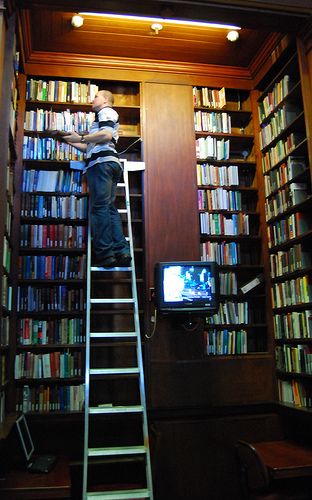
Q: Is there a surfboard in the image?
A: No, there are no surfboards.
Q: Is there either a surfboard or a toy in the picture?
A: No, there are no surfboards or toys.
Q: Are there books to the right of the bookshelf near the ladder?
A: Yes, there is a book to the right of the bookshelf.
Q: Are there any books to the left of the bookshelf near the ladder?
A: No, the book is to the right of the bookshelf.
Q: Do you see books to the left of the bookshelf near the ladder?
A: No, the book is to the right of the bookshelf.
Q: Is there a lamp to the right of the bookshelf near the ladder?
A: No, there is a book to the right of the bookshelf.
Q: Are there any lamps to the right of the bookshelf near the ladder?
A: No, there is a book to the right of the bookshelf.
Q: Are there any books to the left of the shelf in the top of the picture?
A: Yes, there is a book to the left of the shelf.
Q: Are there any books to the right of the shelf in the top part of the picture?
A: No, the book is to the left of the shelf.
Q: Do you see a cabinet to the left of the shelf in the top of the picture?
A: No, there is a book to the left of the shelf.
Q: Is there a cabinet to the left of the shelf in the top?
A: No, there is a book to the left of the shelf.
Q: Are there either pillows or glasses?
A: No, there are no glasses or pillows.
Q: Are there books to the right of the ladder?
A: Yes, there is a book to the right of the ladder.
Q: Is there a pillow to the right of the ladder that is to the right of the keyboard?
A: No, there is a book to the right of the ladder.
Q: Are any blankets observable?
A: No, there are no blankets.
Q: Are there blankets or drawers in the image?
A: No, there are no blankets or drawers.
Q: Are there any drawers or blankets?
A: No, there are no blankets or drawers.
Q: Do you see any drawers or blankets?
A: No, there are no blankets or drawers.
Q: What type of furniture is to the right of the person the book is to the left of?
A: The piece of furniture is a bookshelf.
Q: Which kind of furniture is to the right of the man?
A: The piece of furniture is a bookshelf.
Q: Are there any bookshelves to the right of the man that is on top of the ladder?
A: Yes, there is a bookshelf to the right of the man.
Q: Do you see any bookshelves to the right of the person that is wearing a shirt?
A: Yes, there is a bookshelf to the right of the man.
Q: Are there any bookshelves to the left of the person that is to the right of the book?
A: No, the bookshelf is to the right of the man.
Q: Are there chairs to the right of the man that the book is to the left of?
A: No, there is a bookshelf to the right of the man.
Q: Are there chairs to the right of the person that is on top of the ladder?
A: No, there is a bookshelf to the right of the man.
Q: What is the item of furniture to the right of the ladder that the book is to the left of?
A: The piece of furniture is a bookshelf.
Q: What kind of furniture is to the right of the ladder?
A: The piece of furniture is a bookshelf.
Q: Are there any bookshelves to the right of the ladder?
A: Yes, there is a bookshelf to the right of the ladder.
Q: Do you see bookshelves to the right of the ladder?
A: Yes, there is a bookshelf to the right of the ladder.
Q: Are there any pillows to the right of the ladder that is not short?
A: No, there is a bookshelf to the right of the ladder.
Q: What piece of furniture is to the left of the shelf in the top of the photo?
A: The piece of furniture is a bookshelf.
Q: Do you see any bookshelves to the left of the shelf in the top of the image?
A: Yes, there is a bookshelf to the left of the shelf.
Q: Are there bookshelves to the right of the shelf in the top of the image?
A: No, the bookshelf is to the left of the shelf.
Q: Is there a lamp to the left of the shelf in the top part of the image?
A: No, there is a bookshelf to the left of the shelf.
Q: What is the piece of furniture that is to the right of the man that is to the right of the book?
A: The piece of furniture is a bookshelf.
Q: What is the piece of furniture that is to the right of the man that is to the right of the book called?
A: The piece of furniture is a bookshelf.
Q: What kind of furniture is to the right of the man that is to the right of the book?
A: The piece of furniture is a bookshelf.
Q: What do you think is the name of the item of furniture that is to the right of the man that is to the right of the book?
A: The piece of furniture is a bookshelf.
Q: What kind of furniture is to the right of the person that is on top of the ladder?
A: The piece of furniture is a bookshelf.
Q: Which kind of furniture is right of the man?
A: The piece of furniture is a bookshelf.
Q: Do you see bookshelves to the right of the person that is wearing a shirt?
A: Yes, there is a bookshelf to the right of the man.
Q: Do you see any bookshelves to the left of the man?
A: No, the bookshelf is to the right of the man.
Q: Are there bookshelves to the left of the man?
A: No, the bookshelf is to the right of the man.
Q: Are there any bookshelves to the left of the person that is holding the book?
A: No, the bookshelf is to the right of the man.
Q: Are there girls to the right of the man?
A: No, there is a bookshelf to the right of the man.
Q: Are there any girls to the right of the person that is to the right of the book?
A: No, there is a bookshelf to the right of the man.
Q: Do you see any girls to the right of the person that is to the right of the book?
A: No, there is a bookshelf to the right of the man.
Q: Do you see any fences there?
A: No, there are no fences.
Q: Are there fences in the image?
A: No, there are no fences.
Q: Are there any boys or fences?
A: No, there are no fences or boys.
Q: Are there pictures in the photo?
A: No, there are no pictures.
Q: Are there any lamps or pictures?
A: No, there are no pictures or lamps.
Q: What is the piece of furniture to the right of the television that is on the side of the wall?
A: The piece of furniture is a bookshelf.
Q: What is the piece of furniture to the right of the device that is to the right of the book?
A: The piece of furniture is a bookshelf.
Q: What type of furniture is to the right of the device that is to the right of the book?
A: The piece of furniture is a bookshelf.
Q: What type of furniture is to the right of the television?
A: The piece of furniture is a bookshelf.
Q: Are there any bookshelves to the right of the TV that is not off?
A: Yes, there is a bookshelf to the right of the television.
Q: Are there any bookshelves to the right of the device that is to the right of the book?
A: Yes, there is a bookshelf to the right of the television.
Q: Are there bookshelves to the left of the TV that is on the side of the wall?
A: No, the bookshelf is to the right of the TV.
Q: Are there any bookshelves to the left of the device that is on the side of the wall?
A: No, the bookshelf is to the right of the TV.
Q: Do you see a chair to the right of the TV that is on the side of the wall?
A: No, there is a bookshelf to the right of the TV.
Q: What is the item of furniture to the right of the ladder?
A: The piece of furniture is a bookshelf.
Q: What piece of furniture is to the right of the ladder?
A: The piece of furniture is a bookshelf.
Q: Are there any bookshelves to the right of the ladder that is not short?
A: Yes, there is a bookshelf to the right of the ladder.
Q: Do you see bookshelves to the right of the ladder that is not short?
A: Yes, there is a bookshelf to the right of the ladder.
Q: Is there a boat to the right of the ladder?
A: No, there is a bookshelf to the right of the ladder.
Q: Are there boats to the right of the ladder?
A: No, there is a bookshelf to the right of the ladder.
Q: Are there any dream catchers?
A: No, there are no dream catchers.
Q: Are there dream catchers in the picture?
A: No, there are no dream catchers.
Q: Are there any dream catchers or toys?
A: No, there are no dream catchers or toys.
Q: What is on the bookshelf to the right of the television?
A: The book is on the bookshelf.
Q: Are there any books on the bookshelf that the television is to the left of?
A: Yes, there is a book on the bookshelf.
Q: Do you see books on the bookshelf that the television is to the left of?
A: Yes, there is a book on the bookshelf.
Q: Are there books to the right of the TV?
A: Yes, there is a book to the right of the TV.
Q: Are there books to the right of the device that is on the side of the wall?
A: Yes, there is a book to the right of the TV.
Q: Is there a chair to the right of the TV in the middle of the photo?
A: No, there is a book to the right of the television.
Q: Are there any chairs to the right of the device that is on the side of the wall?
A: No, there is a book to the right of the television.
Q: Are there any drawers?
A: No, there are no drawers.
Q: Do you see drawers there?
A: No, there are no drawers.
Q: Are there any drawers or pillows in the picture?
A: No, there are no drawers or pillows.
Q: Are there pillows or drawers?
A: No, there are no drawers or pillows.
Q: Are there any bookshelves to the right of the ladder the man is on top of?
A: Yes, there is a bookshelf to the right of the ladder.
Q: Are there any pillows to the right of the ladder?
A: No, there is a bookshelf to the right of the ladder.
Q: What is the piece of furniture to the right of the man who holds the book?
A: The piece of furniture is a bookshelf.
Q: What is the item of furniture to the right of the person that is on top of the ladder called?
A: The piece of furniture is a bookshelf.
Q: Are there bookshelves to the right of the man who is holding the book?
A: Yes, there is a bookshelf to the right of the man.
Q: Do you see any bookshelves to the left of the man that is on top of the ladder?
A: No, the bookshelf is to the right of the man.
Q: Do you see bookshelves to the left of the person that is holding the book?
A: No, the bookshelf is to the right of the man.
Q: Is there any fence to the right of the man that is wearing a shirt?
A: No, there is a bookshelf to the right of the man.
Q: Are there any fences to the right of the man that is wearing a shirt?
A: No, there is a bookshelf to the right of the man.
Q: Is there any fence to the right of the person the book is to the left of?
A: No, there is a bookshelf to the right of the man.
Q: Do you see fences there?
A: No, there are no fences.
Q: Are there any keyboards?
A: Yes, there is a keyboard.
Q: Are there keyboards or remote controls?
A: Yes, there is a keyboard.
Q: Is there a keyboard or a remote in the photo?
A: Yes, there is a keyboard.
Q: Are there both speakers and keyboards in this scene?
A: No, there is a keyboard but no speakers.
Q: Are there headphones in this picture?
A: No, there are no headphones.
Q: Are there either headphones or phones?
A: No, there are no headphones or phones.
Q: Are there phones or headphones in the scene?
A: No, there are no headphones or phones.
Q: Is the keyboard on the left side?
A: Yes, the keyboard is on the left of the image.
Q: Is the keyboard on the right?
A: No, the keyboard is on the left of the image.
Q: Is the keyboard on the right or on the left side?
A: The keyboard is on the left of the image.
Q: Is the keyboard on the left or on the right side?
A: The keyboard is on the left of the image.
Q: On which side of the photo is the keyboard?
A: The keyboard is on the left of the image.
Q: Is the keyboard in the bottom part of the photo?
A: Yes, the keyboard is in the bottom of the image.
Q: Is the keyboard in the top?
A: No, the keyboard is in the bottom of the image.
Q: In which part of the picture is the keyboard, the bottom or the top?
A: The keyboard is in the bottom of the image.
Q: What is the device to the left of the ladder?
A: The device is a keyboard.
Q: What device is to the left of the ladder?
A: The device is a keyboard.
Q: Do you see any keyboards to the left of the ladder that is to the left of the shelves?
A: Yes, there is a keyboard to the left of the ladder.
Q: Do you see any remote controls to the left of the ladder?
A: No, there is a keyboard to the left of the ladder.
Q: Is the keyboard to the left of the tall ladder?
A: Yes, the keyboard is to the left of the ladder.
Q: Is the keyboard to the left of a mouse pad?
A: No, the keyboard is to the left of the ladder.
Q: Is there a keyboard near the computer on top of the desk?
A: Yes, there is a keyboard near the computer.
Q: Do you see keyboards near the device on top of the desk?
A: Yes, there is a keyboard near the computer.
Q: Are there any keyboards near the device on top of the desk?
A: Yes, there is a keyboard near the computer.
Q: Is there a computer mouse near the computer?
A: No, there is a keyboard near the computer.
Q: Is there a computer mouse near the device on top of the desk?
A: No, there is a keyboard near the computer.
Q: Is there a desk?
A: Yes, there is a desk.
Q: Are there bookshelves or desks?
A: Yes, there is a desk.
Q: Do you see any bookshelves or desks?
A: Yes, there is a desk.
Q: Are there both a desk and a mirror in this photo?
A: No, there is a desk but no mirrors.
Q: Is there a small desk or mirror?
A: Yes, there is a small desk.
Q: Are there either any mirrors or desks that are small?
A: Yes, the desk is small.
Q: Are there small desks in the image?
A: Yes, there is a small desk.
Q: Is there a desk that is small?
A: Yes, there is a desk that is small.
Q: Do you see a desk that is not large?
A: Yes, there is a small desk.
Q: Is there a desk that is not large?
A: Yes, there is a small desk.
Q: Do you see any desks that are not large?
A: Yes, there is a small desk.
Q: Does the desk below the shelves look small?
A: Yes, the desk is small.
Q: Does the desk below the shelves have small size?
A: Yes, the desk is small.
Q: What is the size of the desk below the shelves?
A: The desk is small.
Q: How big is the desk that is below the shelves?
A: The desk is small.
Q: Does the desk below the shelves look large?
A: No, the desk is small.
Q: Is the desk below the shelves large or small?
A: The desk is small.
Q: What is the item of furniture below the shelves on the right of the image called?
A: The piece of furniture is a desk.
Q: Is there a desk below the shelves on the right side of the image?
A: Yes, there is a desk below the shelves.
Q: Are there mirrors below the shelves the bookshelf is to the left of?
A: No, there is a desk below the shelves.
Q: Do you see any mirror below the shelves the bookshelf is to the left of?
A: No, there is a desk below the shelves.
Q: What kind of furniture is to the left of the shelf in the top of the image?
A: The piece of furniture is a bookshelf.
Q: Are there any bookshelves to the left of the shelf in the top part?
A: Yes, there is a bookshelf to the left of the shelf.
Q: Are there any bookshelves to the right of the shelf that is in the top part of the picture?
A: No, the bookshelf is to the left of the shelf.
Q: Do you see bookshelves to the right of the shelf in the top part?
A: No, the bookshelf is to the left of the shelf.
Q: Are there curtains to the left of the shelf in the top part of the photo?
A: No, there is a bookshelf to the left of the shelf.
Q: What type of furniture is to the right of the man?
A: The piece of furniture is a bookshelf.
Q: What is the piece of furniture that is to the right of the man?
A: The piece of furniture is a bookshelf.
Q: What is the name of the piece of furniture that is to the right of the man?
A: The piece of furniture is a bookshelf.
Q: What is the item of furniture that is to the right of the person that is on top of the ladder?
A: The piece of furniture is a bookshelf.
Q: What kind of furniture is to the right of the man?
A: The piece of furniture is a bookshelf.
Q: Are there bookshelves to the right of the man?
A: Yes, there is a bookshelf to the right of the man.